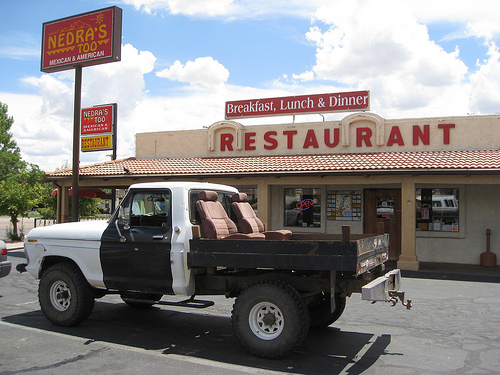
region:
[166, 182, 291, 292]
two cars seats in the back of a truck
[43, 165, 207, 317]
a white truck with a black door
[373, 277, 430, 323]
a trailer hitch on the bumper of a truck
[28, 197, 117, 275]
a white hood on a truck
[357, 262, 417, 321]
a metal bumper on a truck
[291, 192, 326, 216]
a neon open sign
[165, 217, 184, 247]
a gas cap on a truck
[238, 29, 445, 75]
white clouds in a blue sky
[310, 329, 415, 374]
a shadow on a parking lot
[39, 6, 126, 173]
a tall restaurant sign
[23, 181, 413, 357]
Black and white pickup truck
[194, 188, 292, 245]
Two car seats in the back of a pickup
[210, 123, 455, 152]
Large red capital letters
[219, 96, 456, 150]
Red restaurant signs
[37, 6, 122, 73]
Red sign with yellow writing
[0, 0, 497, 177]
White clouds in a sunny sky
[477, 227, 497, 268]
Cigarette butt dispenser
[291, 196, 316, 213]
Blue and red neon open sign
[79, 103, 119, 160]
Red and yellow Mexican restaurant signs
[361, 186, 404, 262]
Wooden entrance door to a restaurant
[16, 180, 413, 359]
white and black truck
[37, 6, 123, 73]
tallest sign behind the truck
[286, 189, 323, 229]
restaurant window with neon open sign in it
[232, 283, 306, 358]
truck's back tire in the foreground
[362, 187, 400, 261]
door of the restaurant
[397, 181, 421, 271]
the piller to right of restaurant door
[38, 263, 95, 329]
front tire of the truck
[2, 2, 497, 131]
sky above the restaurant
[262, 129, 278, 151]
letter "s" on the building behind the truck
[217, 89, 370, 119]
red and white sign above the restaurant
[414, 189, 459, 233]
the window of a restaurant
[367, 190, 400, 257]
a brown door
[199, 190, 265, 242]
a car seat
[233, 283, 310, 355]
a large truck tire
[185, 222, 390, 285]
the bed of a truck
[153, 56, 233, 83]
a small white cloud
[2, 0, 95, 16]
part of a blue sky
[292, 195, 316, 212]
a blue and red open sign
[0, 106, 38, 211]
part of a tall green tree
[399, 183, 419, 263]
a beige building column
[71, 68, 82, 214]
An iron sign post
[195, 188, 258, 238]
Two seats in the rear of a truck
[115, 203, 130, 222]
A metallic side mirror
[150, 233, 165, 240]
A metallic door handle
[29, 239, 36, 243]
The front left flasher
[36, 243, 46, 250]
A rusty dent on the truck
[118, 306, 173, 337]
Shadow cas by the truck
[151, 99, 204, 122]
White clouds in the sky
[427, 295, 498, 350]
Sun shining on the parking lot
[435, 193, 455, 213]
Car reflection in the window